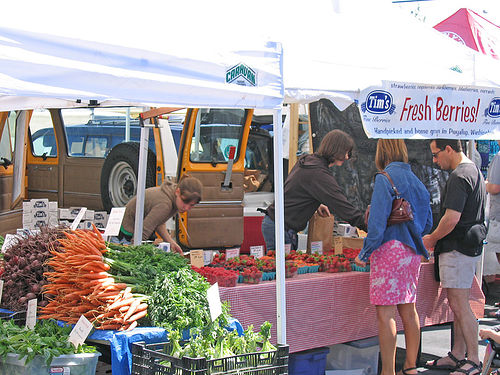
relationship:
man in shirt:
[423, 138, 488, 374] [432, 161, 489, 257]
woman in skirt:
[354, 140, 432, 375] [366, 239, 426, 306]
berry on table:
[327, 256, 336, 269] [205, 265, 376, 291]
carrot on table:
[80, 264, 108, 274] [205, 265, 376, 291]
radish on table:
[29, 280, 43, 296] [205, 265, 376, 291]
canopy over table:
[280, 0, 498, 112] [205, 265, 376, 291]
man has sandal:
[423, 138, 488, 374] [426, 352, 466, 367]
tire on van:
[100, 141, 157, 215] [1, 106, 254, 256]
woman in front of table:
[354, 140, 432, 375] [205, 265, 376, 291]